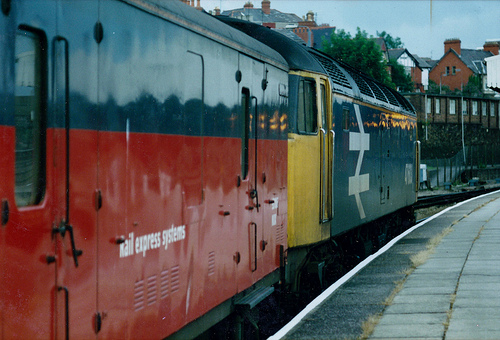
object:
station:
[0, 0, 499, 340]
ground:
[436, 251, 465, 271]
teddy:
[382, 66, 391, 72]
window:
[293, 78, 318, 133]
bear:
[381, 43, 389, 52]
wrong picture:
[160, 94, 250, 198]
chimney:
[261, 0, 271, 15]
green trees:
[317, 26, 415, 93]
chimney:
[443, 38, 461, 56]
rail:
[327, 129, 334, 219]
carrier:
[0, 0, 420, 340]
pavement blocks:
[369, 199, 499, 340]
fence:
[398, 93, 500, 191]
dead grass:
[407, 251, 424, 265]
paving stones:
[402, 296, 471, 315]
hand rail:
[49, 224, 79, 269]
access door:
[0, 0, 72, 340]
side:
[0, 0, 423, 340]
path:
[264, 190, 500, 340]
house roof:
[429, 47, 494, 75]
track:
[415, 191, 492, 210]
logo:
[119, 223, 185, 259]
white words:
[119, 222, 189, 258]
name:
[119, 223, 186, 258]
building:
[428, 38, 500, 94]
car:
[215, 14, 419, 248]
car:
[0, 0, 290, 340]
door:
[320, 77, 334, 222]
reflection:
[21, 155, 287, 340]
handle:
[319, 127, 327, 222]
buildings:
[182, 0, 334, 48]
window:
[11, 24, 47, 209]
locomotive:
[0, 0, 422, 340]